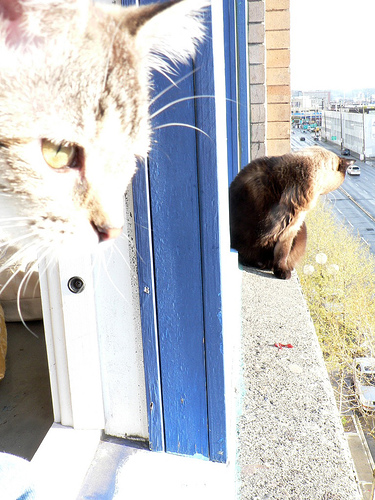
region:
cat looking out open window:
[0, 4, 227, 494]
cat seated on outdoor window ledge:
[234, 49, 364, 496]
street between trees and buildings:
[286, 92, 371, 269]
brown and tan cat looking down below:
[233, 144, 357, 298]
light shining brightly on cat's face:
[3, 2, 210, 334]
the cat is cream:
[232, 128, 358, 283]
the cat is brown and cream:
[227, 124, 352, 287]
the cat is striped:
[18, 11, 211, 283]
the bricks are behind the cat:
[252, 13, 353, 305]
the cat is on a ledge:
[233, 127, 351, 488]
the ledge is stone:
[250, 284, 349, 490]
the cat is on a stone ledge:
[241, 139, 355, 489]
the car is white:
[352, 350, 371, 427]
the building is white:
[317, 99, 368, 162]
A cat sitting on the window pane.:
[250, 133, 327, 293]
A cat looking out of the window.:
[15, 58, 111, 250]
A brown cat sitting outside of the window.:
[250, 159, 305, 268]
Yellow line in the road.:
[346, 191, 362, 227]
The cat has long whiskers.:
[12, 224, 46, 311]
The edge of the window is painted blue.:
[142, 180, 219, 422]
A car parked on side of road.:
[353, 362, 373, 409]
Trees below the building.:
[312, 227, 359, 339]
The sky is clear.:
[301, 22, 358, 84]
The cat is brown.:
[250, 162, 312, 221]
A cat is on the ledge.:
[231, 146, 353, 281]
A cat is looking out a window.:
[4, 2, 205, 262]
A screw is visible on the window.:
[66, 279, 86, 295]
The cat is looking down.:
[230, 141, 353, 281]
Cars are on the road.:
[346, 164, 362, 175]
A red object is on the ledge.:
[271, 341, 292, 351]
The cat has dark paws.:
[274, 258, 293, 283]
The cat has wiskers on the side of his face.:
[143, 62, 248, 141]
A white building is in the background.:
[322, 107, 373, 162]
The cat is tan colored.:
[227, 145, 350, 280]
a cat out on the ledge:
[228, 145, 354, 282]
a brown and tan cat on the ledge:
[231, 146, 346, 280]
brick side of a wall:
[250, 0, 290, 160]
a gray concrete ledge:
[239, 262, 361, 497]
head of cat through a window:
[0, 0, 210, 280]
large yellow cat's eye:
[41, 139, 76, 169]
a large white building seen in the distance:
[321, 105, 372, 157]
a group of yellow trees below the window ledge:
[296, 201, 373, 432]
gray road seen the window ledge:
[290, 124, 373, 244]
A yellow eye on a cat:
[38, 137, 83, 173]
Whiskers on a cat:
[154, 64, 245, 140]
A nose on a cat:
[100, 228, 119, 241]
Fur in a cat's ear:
[155, 29, 206, 79]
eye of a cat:
[40, 135, 81, 170]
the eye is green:
[43, 140, 85, 167]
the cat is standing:
[226, 143, 350, 278]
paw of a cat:
[276, 263, 289, 278]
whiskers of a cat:
[0, 226, 68, 322]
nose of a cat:
[95, 221, 123, 248]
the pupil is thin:
[55, 143, 62, 153]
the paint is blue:
[120, 0, 228, 460]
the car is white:
[349, 163, 360, 176]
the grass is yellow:
[289, 198, 373, 360]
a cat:
[243, 144, 337, 276]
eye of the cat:
[38, 134, 90, 181]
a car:
[352, 355, 373, 401]